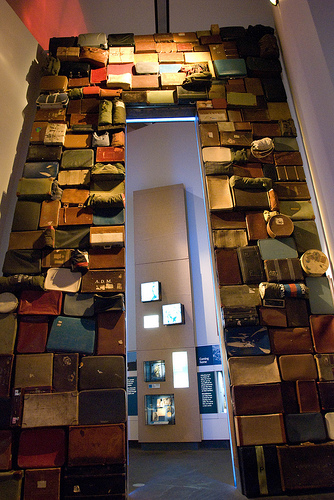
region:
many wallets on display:
[9, 21, 332, 498]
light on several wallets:
[89, 25, 241, 108]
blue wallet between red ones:
[40, 313, 101, 357]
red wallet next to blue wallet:
[12, 314, 54, 354]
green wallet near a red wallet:
[60, 146, 99, 170]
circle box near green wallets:
[265, 210, 295, 242]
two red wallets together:
[6, 424, 122, 470]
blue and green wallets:
[16, 160, 63, 199]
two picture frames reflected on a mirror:
[134, 275, 188, 331]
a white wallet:
[203, 170, 238, 211]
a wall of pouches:
[33, 377, 87, 450]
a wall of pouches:
[279, 372, 310, 468]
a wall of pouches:
[260, 423, 309, 489]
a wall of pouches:
[239, 375, 299, 479]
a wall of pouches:
[257, 381, 285, 461]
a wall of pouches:
[232, 409, 266, 468]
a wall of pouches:
[274, 364, 301, 432]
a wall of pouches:
[242, 378, 281, 446]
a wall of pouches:
[300, 341, 312, 445]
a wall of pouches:
[291, 354, 302, 442]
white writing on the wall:
[161, 340, 227, 462]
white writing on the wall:
[185, 316, 239, 473]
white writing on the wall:
[206, 351, 249, 487]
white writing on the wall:
[185, 253, 236, 422]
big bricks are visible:
[215, 291, 280, 429]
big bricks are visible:
[197, 370, 281, 494]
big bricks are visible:
[235, 275, 297, 469]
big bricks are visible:
[249, 344, 308, 494]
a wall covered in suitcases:
[13, 25, 331, 488]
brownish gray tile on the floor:
[151, 456, 208, 488]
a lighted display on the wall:
[144, 390, 189, 428]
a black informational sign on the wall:
[197, 371, 222, 423]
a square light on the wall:
[132, 308, 167, 330]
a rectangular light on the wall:
[167, 344, 192, 391]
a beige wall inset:
[139, 191, 190, 264]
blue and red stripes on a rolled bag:
[281, 282, 301, 295]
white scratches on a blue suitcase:
[230, 334, 260, 349]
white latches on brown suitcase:
[13, 385, 18, 429]